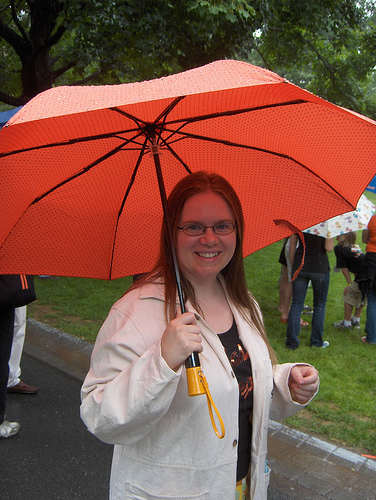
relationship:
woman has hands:
[79, 143, 301, 500] [171, 293, 208, 372]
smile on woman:
[185, 242, 233, 268] [79, 143, 301, 500]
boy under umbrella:
[341, 258, 374, 299] [2, 28, 363, 279]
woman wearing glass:
[79, 143, 301, 500] [162, 184, 258, 246]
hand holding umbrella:
[174, 302, 213, 356] [2, 28, 363, 279]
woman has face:
[79, 143, 301, 500] [189, 198, 243, 265]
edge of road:
[50, 358, 71, 406] [17, 349, 91, 481]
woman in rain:
[79, 143, 301, 500] [32, 20, 320, 180]